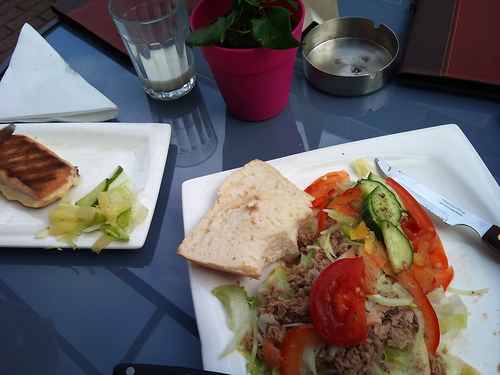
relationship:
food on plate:
[173, 156, 478, 373] [181, 120, 498, 373]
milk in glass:
[132, 37, 195, 92] [106, 0, 201, 105]